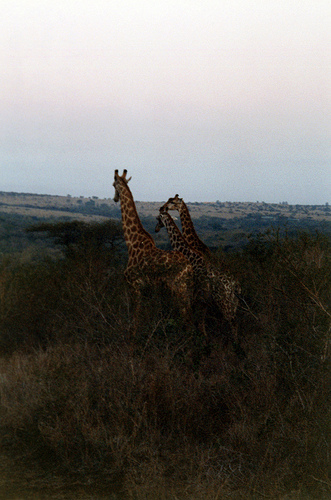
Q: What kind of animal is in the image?
A: Giraffe.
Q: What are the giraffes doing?
A: Standing in the field.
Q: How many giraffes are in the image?
A: Three.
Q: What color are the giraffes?
A: White and brown.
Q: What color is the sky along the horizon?
A: Blue.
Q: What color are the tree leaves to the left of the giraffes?
A: Green.